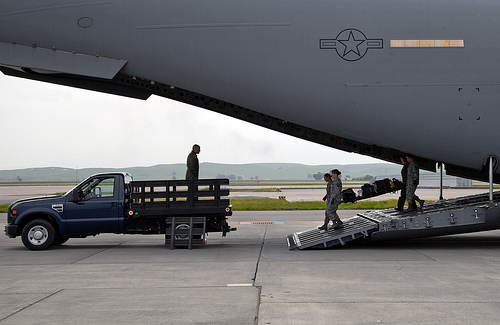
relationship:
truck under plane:
[5, 172, 235, 249] [1, 0, 490, 160]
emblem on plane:
[316, 27, 386, 62] [19, 4, 496, 176]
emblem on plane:
[318, 27, 384, 61] [1, 0, 498, 249]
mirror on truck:
[69, 187, 82, 201] [1, 145, 252, 251]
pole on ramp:
[485, 161, 497, 198] [277, 190, 497, 255]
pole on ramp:
[436, 165, 445, 200] [277, 190, 497, 255]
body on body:
[345, 176, 406, 203] [341, 178, 405, 204]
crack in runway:
[252, 217, 268, 319] [0, 206, 496, 323]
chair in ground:
[165, 216, 206, 250] [8, 152, 493, 304]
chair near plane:
[165, 216, 206, 250] [1, 0, 498, 249]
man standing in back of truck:
[185, 142, 200, 197] [4, 172, 237, 251]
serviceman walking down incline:
[403, 149, 421, 214] [287, 189, 497, 258]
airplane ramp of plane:
[286, 191, 500, 251] [1, 0, 498, 249]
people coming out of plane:
[317, 154, 425, 230] [1, 0, 498, 249]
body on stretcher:
[341, 178, 405, 204] [337, 177, 409, 207]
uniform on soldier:
[327, 178, 342, 227] [326, 169, 344, 229]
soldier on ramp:
[326, 169, 344, 229] [285, 188, 499, 272]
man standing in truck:
[185, 144, 200, 201] [4, 172, 237, 251]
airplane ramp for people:
[286, 191, 500, 251] [289, 213, 380, 253]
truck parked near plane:
[4, 172, 237, 251] [1, 0, 498, 249]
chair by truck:
[165, 216, 206, 250] [5, 172, 235, 249]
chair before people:
[162, 213, 209, 251] [316, 150, 425, 233]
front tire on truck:
[20, 219, 55, 251] [5, 172, 235, 249]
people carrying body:
[321, 153, 424, 231] [341, 178, 405, 204]